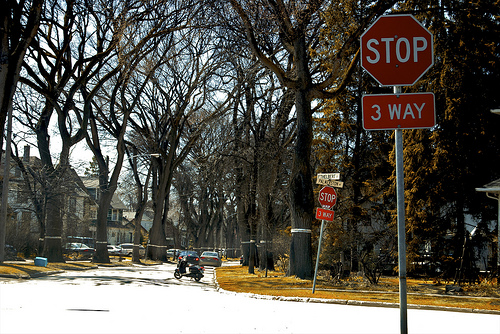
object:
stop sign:
[360, 14, 435, 88]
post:
[391, 87, 408, 334]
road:
[0, 259, 500, 334]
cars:
[199, 250, 223, 267]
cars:
[60, 242, 97, 258]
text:
[365, 37, 428, 65]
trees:
[413, 0, 499, 280]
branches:
[157, 28, 197, 66]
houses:
[0, 150, 48, 250]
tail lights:
[213, 258, 219, 261]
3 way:
[371, 102, 428, 121]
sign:
[359, 91, 436, 131]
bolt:
[395, 95, 401, 99]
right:
[334, 0, 500, 333]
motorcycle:
[173, 254, 207, 282]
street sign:
[317, 172, 341, 179]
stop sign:
[318, 185, 338, 209]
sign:
[314, 207, 335, 223]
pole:
[310, 219, 326, 294]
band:
[290, 228, 311, 233]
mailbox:
[122, 248, 128, 254]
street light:
[149, 153, 160, 159]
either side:
[213, 0, 499, 316]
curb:
[212, 267, 500, 316]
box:
[34, 256, 48, 267]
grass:
[0, 261, 96, 276]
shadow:
[0, 263, 181, 287]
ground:
[0, 260, 500, 334]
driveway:
[58, 236, 227, 258]